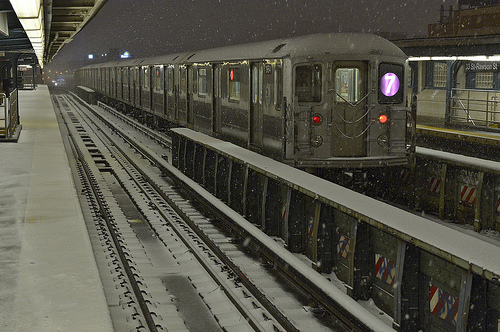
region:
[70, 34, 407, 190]
train heading to the right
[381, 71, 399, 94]
a round purple number seven indicating the number of the train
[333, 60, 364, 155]
a door to the front or end of the train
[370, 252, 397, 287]
red and white stripped signs with graffiti on them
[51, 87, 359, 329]
an empty rail road track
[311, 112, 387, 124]
two red lights on the end of the train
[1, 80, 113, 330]
an empty platform were people get on and off of the tain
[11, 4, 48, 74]
a row of lights running along the platform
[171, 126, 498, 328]
a short wall separating the train tracks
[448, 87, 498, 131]
a hand tail for people to use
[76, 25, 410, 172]
A subway train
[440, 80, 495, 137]
A metal guard rail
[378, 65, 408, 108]
A white number seven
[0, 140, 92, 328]
Snow on the platform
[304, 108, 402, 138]
Red lights on the train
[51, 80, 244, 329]
Snow on the subway tracks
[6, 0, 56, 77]
A row of lights lighting the paltform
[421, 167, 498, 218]
Red and white striped warning signs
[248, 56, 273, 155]
A train door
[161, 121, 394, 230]
The track divider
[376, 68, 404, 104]
bright pink neon circle with number seven in the middle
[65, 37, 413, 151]
large silver train with many compartments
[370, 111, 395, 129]
small red light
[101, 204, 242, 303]
train tracks with white snow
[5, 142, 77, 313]
solid white pavement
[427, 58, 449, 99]
window compartment with white squares and green edgings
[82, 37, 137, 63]
overhead blue lighting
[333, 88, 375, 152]
three silver chains across the front of train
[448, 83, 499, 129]
large square barrier with lines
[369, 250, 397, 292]
large red and white lines with graffiti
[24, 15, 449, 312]
snow covering train, rails and platform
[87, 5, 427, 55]
faint lights of city skyline behind train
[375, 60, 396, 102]
number and color of train route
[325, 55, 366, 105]
front window showing poster inside train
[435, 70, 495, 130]
metal railing for staircase to exit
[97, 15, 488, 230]
train moving on middle track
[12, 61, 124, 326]
no passengers on platform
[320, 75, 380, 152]
three ropes covering door of first car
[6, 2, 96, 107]
roof supporting row of lights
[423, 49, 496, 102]
windows of glass blocks in wall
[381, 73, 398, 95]
The number seven in a purple circle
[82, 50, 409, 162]
A subway or normal train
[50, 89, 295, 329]
A set of train tracks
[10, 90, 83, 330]
The waiting platform beside the train stop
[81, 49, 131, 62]
Lights of a city in the distance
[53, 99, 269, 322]
Empty train tracks beside a train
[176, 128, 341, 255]
A barrier between two train tracks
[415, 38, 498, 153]
A building in the train station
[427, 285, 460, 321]
Red and white striped sign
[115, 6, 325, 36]
The dark night sky